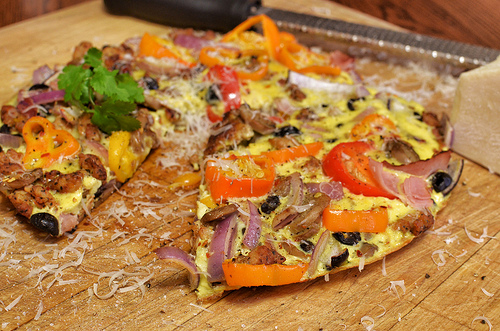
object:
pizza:
[0, 14, 466, 304]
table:
[0, 0, 500, 331]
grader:
[251, 5, 498, 76]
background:
[0, 0, 499, 109]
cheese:
[108, 203, 167, 237]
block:
[450, 55, 500, 177]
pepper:
[21, 116, 81, 172]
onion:
[207, 211, 241, 283]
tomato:
[321, 141, 400, 200]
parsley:
[56, 47, 146, 136]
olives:
[29, 211, 79, 238]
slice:
[53, 135, 65, 149]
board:
[151, 303, 322, 328]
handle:
[102, 0, 263, 34]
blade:
[253, 7, 500, 77]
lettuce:
[86, 93, 141, 134]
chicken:
[203, 108, 273, 160]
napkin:
[455, 57, 499, 107]